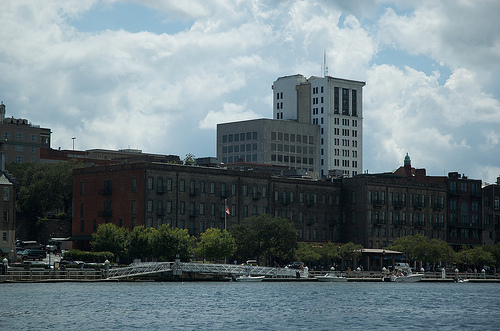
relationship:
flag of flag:
[217, 195, 235, 218] [223, 202, 231, 214]